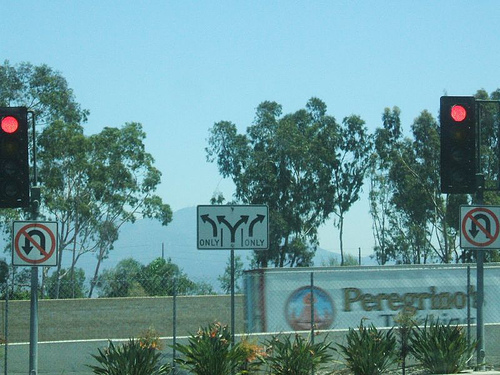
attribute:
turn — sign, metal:
[168, 195, 269, 271]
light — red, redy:
[443, 97, 474, 125]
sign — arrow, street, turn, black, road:
[195, 198, 275, 254]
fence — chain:
[91, 280, 127, 321]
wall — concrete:
[94, 233, 186, 315]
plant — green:
[101, 223, 170, 277]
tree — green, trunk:
[217, 89, 359, 301]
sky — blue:
[186, 26, 254, 93]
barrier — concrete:
[201, 272, 331, 357]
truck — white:
[228, 239, 414, 351]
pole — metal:
[456, 245, 489, 356]